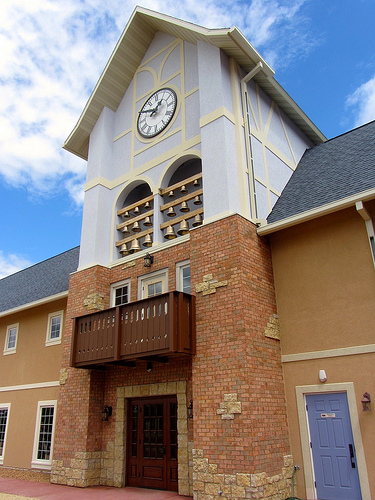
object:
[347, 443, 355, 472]
handle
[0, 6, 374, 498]
building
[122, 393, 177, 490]
door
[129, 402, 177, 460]
windows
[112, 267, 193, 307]
windows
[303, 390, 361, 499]
door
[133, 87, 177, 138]
clock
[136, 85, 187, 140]
clock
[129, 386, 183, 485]
door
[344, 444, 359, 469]
handle of the door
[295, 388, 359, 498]
door at the bottom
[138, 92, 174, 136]
black numbers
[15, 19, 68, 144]
clouds in the sky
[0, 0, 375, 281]
blue sky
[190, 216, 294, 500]
bricks on the wall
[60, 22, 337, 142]
top of the building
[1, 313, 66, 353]
two windows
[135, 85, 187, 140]
clock on the house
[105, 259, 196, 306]
three windows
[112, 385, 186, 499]
door in brick wall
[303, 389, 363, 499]
blue door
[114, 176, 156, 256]
nine bells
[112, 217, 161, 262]
six bells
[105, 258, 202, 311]
three windows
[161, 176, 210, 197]
three bells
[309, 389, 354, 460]
purple door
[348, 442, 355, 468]
black door knob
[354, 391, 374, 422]
light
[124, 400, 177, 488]
burgundy door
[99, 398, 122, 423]
light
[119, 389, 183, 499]
main door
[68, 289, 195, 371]
brown balcony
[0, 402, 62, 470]
windows on the left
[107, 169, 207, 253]
golden bells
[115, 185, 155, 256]
golden bells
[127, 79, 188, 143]
clock on building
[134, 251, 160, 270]
lamp above balcony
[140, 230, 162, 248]
gold bell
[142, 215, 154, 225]
"gold bell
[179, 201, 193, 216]
gold bell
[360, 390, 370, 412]
"small lamp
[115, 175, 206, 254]
set of gold bells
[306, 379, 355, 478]
blue door on buildin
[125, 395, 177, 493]
"brown door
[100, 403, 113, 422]
black light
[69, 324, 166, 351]
brown deck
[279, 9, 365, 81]
sunny blue sky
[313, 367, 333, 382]
white light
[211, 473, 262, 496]
tan bricks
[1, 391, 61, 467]
two windows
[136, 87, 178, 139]
black and white